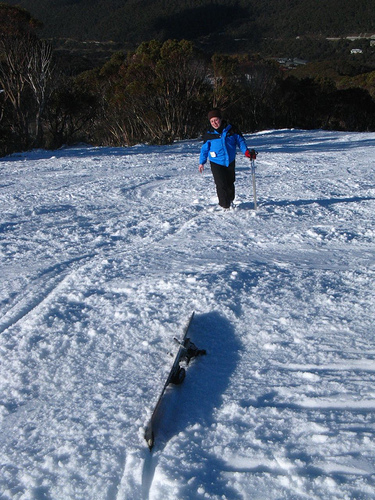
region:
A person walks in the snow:
[192, 108, 263, 215]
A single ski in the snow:
[140, 304, 205, 449]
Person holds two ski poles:
[245, 144, 263, 212]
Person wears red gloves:
[245, 146, 257, 162]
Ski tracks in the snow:
[4, 219, 100, 345]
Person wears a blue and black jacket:
[195, 126, 256, 171]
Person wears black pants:
[210, 160, 237, 210]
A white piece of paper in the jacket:
[210, 151, 218, 158]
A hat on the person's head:
[209, 111, 224, 131]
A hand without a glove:
[199, 158, 206, 176]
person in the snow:
[122, 82, 289, 271]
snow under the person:
[233, 213, 314, 270]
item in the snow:
[129, 293, 258, 434]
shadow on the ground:
[194, 316, 260, 424]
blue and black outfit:
[189, 105, 270, 190]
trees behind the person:
[107, 40, 209, 137]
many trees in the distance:
[60, 11, 113, 43]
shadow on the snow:
[289, 127, 355, 168]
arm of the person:
[182, 134, 216, 184]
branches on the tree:
[140, 83, 196, 136]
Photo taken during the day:
[0, 8, 369, 488]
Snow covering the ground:
[24, 157, 360, 488]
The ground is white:
[10, 145, 370, 483]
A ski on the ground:
[128, 297, 220, 462]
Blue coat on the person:
[186, 124, 261, 172]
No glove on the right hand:
[191, 157, 206, 176]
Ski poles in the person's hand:
[242, 142, 261, 211]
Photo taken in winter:
[6, 18, 365, 488]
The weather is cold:
[4, 16, 361, 493]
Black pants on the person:
[198, 153, 249, 210]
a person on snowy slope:
[197, 112, 260, 206]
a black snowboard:
[138, 309, 208, 452]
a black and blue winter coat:
[198, 126, 248, 166]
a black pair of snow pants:
[210, 157, 238, 207]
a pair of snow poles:
[248, 152, 259, 206]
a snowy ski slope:
[1, 127, 373, 498]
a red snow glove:
[243, 146, 255, 159]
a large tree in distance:
[112, 40, 207, 139]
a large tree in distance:
[54, 66, 100, 144]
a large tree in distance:
[23, 35, 62, 147]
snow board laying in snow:
[139, 308, 215, 470]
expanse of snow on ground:
[3, 123, 374, 498]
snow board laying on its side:
[133, 307, 208, 450]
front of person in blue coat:
[191, 109, 262, 216]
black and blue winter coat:
[194, 123, 255, 173]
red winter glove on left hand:
[243, 146, 257, 160]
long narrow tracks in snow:
[2, 169, 205, 359]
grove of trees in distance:
[3, 8, 374, 154]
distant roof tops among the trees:
[265, 53, 312, 70]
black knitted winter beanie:
[204, 107, 223, 124]